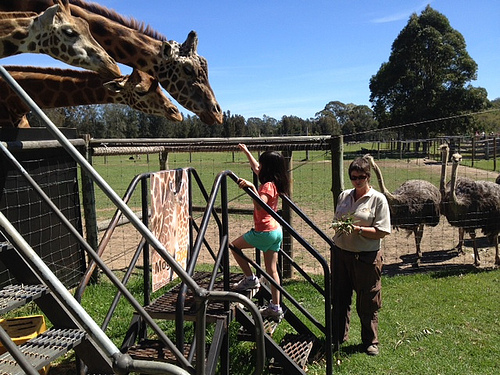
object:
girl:
[228, 140, 290, 317]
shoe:
[358, 337, 381, 353]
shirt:
[253, 181, 278, 231]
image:
[152, 167, 192, 251]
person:
[329, 155, 392, 355]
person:
[226, 141, 288, 323]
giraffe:
[118, 36, 210, 113]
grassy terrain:
[92, 134, 499, 373]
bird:
[445, 152, 499, 266]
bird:
[435, 143, 500, 254]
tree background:
[361, 2, 486, 141]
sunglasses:
[349, 171, 371, 183]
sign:
[147, 167, 191, 291]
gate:
[0, 165, 331, 372]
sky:
[1, 0, 497, 130]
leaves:
[335, 222, 351, 231]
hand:
[335, 222, 362, 237]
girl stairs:
[228, 141, 319, 323]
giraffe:
[4, 6, 127, 81]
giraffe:
[0, 56, 189, 131]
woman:
[225, 148, 291, 323]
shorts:
[239, 221, 286, 256]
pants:
[320, 239, 387, 347]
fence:
[85, 150, 476, 266]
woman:
[323, 151, 402, 352]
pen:
[11, 119, 498, 369]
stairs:
[138, 260, 326, 373]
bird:
[360, 149, 441, 267]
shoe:
[254, 306, 285, 327]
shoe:
[232, 275, 261, 289]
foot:
[365, 342, 379, 356]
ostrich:
[363, 155, 440, 269]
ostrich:
[445, 148, 498, 269]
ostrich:
[433, 140, 452, 219]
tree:
[367, 3, 489, 153]